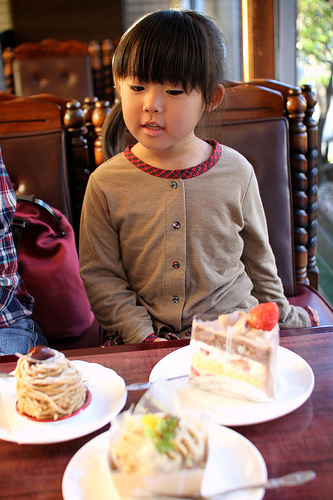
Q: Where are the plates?
A: On the table.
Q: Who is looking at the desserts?
A: A little girl.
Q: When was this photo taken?
A: During the daytime.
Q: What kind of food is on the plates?
A: Desserts.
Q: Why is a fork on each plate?
A: To eat the treat with.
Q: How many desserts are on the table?
A: Three.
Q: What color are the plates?
A: White.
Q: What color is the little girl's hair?
A: Black.